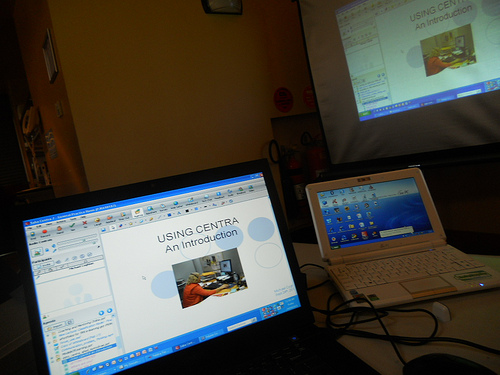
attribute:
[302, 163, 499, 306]
laptop — sitting, white, small, plastic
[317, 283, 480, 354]
cables — black, tangled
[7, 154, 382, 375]
laptop — black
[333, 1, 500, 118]
presentation — projected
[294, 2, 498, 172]
screen — white, large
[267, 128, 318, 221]
fire extinguisher — red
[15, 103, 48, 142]
wall phone — off white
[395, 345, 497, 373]
mouse — black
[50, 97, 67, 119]
switch — white, small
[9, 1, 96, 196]
wall — blank, bare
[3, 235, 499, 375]
table — white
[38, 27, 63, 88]
picture — hanging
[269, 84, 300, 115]
sticker — red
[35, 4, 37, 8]
paint — white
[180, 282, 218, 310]
shirt — orange